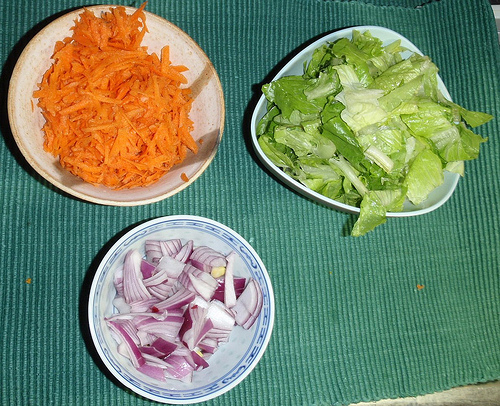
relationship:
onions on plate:
[138, 284, 206, 335] [74, 202, 304, 404]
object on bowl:
[134, 283, 223, 342] [6, 3, 225, 207]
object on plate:
[322, 92, 412, 172] [245, 27, 462, 219]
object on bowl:
[75, 78, 169, 152] [87, 214, 276, 405]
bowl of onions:
[87, 214, 276, 405] [132, 255, 204, 365]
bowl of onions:
[82, 212, 278, 403] [127, 270, 210, 360]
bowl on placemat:
[82, 212, 278, 403] [290, 243, 497, 379]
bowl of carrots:
[6, 3, 226, 206] [56, 66, 179, 166]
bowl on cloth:
[6, 3, 226, 206] [0, 0, 499, 406]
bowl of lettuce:
[247, 23, 467, 217] [226, 34, 457, 216]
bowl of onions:
[249, 25, 464, 217] [130, 259, 214, 368]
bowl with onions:
[249, 25, 464, 217] [120, 274, 214, 355]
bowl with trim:
[249, 25, 464, 217] [236, 338, 265, 371]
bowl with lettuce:
[247, 23, 467, 217] [286, 53, 441, 234]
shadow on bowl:
[188, 133, 217, 163] [6, 3, 225, 207]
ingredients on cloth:
[29, 0, 205, 191] [0, 0, 499, 406]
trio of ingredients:
[30, 5, 482, 383] [27, 0, 204, 192]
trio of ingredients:
[30, 5, 482, 383] [256, 27, 496, 241]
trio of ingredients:
[30, 5, 482, 383] [100, 235, 265, 387]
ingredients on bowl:
[27, 0, 204, 192] [6, 3, 225, 207]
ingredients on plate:
[256, 27, 496, 241] [245, 27, 462, 219]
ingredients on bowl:
[100, 235, 265, 387] [87, 214, 276, 405]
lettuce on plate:
[254, 33, 486, 231] [245, 27, 462, 219]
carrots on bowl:
[32, 5, 198, 186] [6, 3, 225, 207]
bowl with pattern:
[6, 3, 225, 207] [58, 64, 219, 183]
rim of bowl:
[87, 214, 275, 404] [87, 214, 276, 405]